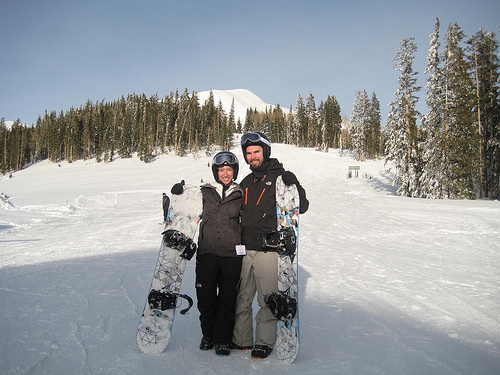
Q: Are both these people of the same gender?
A: No, they are both male and female.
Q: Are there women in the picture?
A: Yes, there is a woman.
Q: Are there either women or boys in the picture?
A: Yes, there is a woman.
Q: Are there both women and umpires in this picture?
A: No, there is a woman but no umpires.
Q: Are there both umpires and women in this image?
A: No, there is a woman but no umpires.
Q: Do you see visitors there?
A: No, there are no visitors.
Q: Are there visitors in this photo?
A: No, there are no visitors.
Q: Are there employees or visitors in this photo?
A: No, there are no visitors or employees.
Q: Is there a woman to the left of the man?
A: Yes, there is a woman to the left of the man.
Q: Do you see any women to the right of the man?
A: No, the woman is to the left of the man.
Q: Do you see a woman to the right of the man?
A: No, the woman is to the left of the man.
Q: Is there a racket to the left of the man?
A: No, there is a woman to the left of the man.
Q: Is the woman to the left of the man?
A: Yes, the woman is to the left of the man.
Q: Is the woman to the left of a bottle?
A: No, the woman is to the left of the man.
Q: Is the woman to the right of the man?
A: No, the woman is to the left of the man.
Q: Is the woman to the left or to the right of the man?
A: The woman is to the left of the man.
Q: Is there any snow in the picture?
A: Yes, there is snow.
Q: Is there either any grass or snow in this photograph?
A: Yes, there is snow.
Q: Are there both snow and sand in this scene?
A: No, there is snow but no sand.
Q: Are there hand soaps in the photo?
A: No, there are no hand soaps.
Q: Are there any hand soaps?
A: No, there are no hand soaps.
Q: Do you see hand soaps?
A: No, there are no hand soaps.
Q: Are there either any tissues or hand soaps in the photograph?
A: No, there are no hand soaps or tissues.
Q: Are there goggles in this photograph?
A: Yes, there are goggles.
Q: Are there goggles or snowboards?
A: Yes, there are goggles.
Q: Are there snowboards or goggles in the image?
A: Yes, there are goggles.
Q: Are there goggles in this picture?
A: Yes, there are goggles.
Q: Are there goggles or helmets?
A: Yes, there are goggles.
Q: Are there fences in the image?
A: No, there are no fences.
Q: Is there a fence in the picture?
A: No, there are no fences.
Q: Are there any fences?
A: No, there are no fences.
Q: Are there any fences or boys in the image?
A: No, there are no fences or boys.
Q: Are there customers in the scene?
A: No, there are no customers.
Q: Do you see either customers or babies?
A: No, there are no customers or babies.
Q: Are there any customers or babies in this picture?
A: No, there are no customers or babies.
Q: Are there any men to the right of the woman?
A: Yes, there is a man to the right of the woman.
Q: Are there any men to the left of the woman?
A: No, the man is to the right of the woman.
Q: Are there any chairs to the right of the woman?
A: No, there is a man to the right of the woman.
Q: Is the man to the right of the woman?
A: Yes, the man is to the right of the woman.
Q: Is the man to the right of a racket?
A: No, the man is to the right of the woman.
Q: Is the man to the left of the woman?
A: No, the man is to the right of the woman.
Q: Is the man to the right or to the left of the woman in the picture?
A: The man is to the right of the woman.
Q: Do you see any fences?
A: No, there are no fences.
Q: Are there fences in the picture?
A: No, there are no fences.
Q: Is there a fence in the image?
A: No, there are no fences.